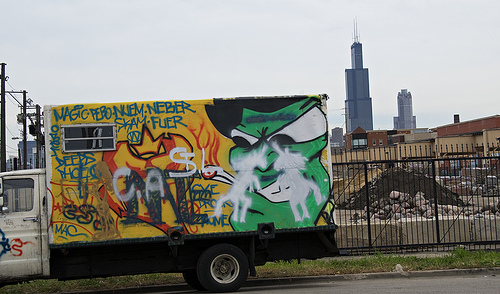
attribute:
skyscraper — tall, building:
[345, 18, 374, 132]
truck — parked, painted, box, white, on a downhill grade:
[0, 94, 340, 292]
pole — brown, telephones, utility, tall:
[36, 104, 42, 171]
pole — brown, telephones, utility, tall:
[23, 91, 28, 170]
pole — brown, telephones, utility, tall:
[0, 63, 7, 172]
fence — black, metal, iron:
[331, 149, 499, 255]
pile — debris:
[363, 191, 460, 220]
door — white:
[0, 173, 42, 277]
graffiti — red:
[11, 237, 34, 260]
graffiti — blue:
[0, 228, 10, 258]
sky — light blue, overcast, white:
[3, 0, 499, 159]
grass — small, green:
[2, 248, 498, 294]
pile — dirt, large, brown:
[336, 167, 466, 209]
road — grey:
[82, 266, 499, 293]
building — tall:
[345, 18, 374, 130]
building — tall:
[392, 90, 416, 130]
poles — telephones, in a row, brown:
[0, 63, 40, 173]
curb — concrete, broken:
[82, 267, 498, 293]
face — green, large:
[230, 96, 327, 231]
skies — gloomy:
[0, 0, 499, 159]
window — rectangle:
[61, 122, 117, 155]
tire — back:
[197, 243, 248, 292]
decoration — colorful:
[47, 94, 337, 247]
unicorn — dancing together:
[271, 140, 326, 224]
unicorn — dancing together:
[213, 141, 269, 225]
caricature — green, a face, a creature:
[228, 96, 332, 235]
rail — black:
[334, 157, 498, 163]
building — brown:
[330, 115, 498, 175]